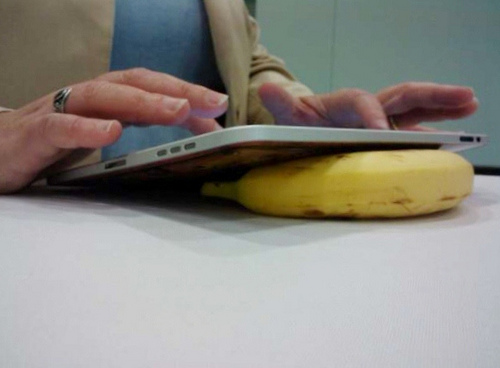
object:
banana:
[195, 146, 475, 220]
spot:
[297, 207, 329, 217]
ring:
[52, 86, 71, 113]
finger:
[49, 81, 192, 126]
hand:
[0, 64, 231, 196]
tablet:
[45, 119, 489, 196]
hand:
[254, 78, 479, 132]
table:
[1, 169, 500, 367]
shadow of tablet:
[79, 185, 484, 266]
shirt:
[110, 0, 217, 162]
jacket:
[0, 1, 316, 177]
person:
[0, 0, 481, 207]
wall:
[243, 0, 499, 170]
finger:
[133, 109, 225, 137]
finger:
[333, 81, 390, 129]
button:
[155, 147, 168, 160]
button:
[168, 144, 182, 155]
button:
[182, 141, 197, 150]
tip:
[198, 176, 223, 200]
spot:
[337, 152, 351, 163]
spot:
[391, 198, 413, 208]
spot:
[438, 195, 456, 204]